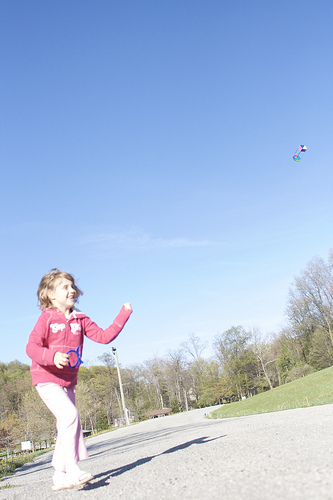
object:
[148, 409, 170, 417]
roof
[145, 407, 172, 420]
house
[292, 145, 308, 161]
kite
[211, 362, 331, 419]
grass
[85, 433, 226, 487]
shadow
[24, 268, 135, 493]
girl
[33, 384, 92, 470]
pants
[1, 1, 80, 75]
sky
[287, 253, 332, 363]
tree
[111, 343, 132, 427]
lamppost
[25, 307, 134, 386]
jacket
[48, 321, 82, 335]
letters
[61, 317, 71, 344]
zipper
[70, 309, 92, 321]
hood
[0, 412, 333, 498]
road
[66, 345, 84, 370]
handle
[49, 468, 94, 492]
shoes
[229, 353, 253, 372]
leaves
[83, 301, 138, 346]
arm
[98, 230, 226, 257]
cloud